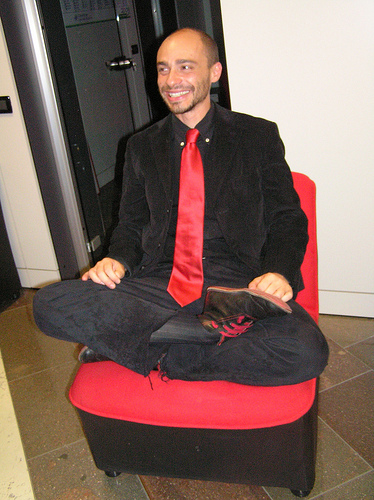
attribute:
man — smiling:
[32, 27, 329, 389]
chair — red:
[67, 170, 319, 498]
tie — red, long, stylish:
[165, 130, 205, 307]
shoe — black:
[196, 285, 292, 349]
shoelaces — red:
[206, 315, 253, 342]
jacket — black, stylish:
[103, 100, 308, 291]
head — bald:
[151, 27, 223, 113]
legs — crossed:
[31, 277, 329, 387]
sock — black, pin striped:
[148, 311, 221, 346]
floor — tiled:
[1, 287, 372, 498]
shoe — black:
[75, 343, 160, 373]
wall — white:
[0, 0, 372, 319]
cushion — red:
[68, 170, 317, 431]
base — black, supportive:
[74, 374, 322, 498]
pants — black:
[31, 272, 327, 384]